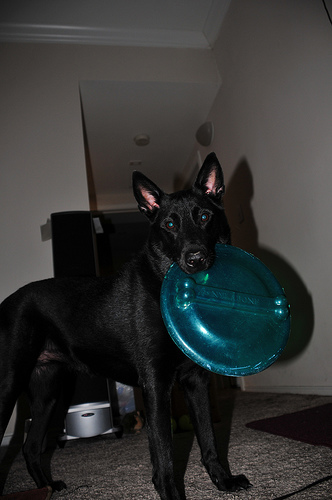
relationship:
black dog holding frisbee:
[0, 151, 253, 500] [157, 240, 297, 381]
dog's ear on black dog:
[192, 152, 226, 200] [0, 151, 253, 500]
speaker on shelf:
[51, 210, 110, 275] [79, 369, 139, 440]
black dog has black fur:
[0, 151, 253, 500] [80, 282, 149, 341]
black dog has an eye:
[0, 151, 253, 500] [196, 212, 211, 226]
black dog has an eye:
[0, 151, 253, 500] [164, 219, 174, 228]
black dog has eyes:
[0, 151, 253, 500] [154, 194, 233, 242]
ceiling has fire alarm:
[78, 82, 223, 213] [134, 134, 150, 147]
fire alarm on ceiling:
[134, 134, 150, 147] [78, 82, 223, 213]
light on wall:
[193, 117, 215, 148] [191, 5, 328, 393]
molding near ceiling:
[24, 21, 206, 36] [0, 0, 202, 31]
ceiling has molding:
[0, 0, 202, 31] [24, 21, 206, 36]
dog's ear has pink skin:
[194, 150, 224, 198] [206, 171, 215, 190]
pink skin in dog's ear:
[206, 171, 215, 190] [194, 150, 224, 198]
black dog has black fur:
[0, 151, 253, 500] [82, 277, 153, 360]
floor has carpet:
[251, 396, 319, 498] [254, 449, 317, 497]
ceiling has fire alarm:
[79, 78, 227, 205] [133, 132, 153, 146]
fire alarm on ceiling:
[133, 132, 153, 146] [79, 78, 227, 205]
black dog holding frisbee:
[0, 151, 253, 498] [158, 242, 290, 376]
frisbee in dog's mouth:
[160, 243, 292, 376] [173, 246, 215, 277]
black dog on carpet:
[0, 151, 253, 500] [1, 396, 319, 495]